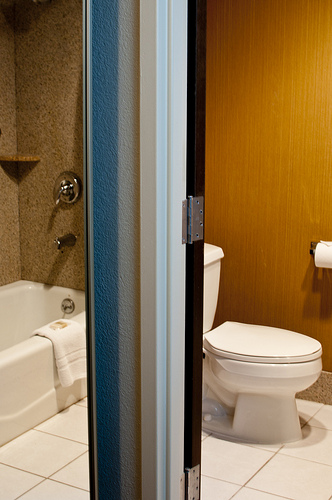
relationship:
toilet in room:
[206, 247, 327, 446] [200, 5, 331, 497]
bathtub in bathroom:
[0, 277, 87, 449] [3, 3, 90, 484]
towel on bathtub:
[34, 317, 85, 407] [4, 277, 81, 442]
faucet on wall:
[53, 230, 76, 255] [15, 6, 85, 284]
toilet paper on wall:
[305, 233, 331, 283] [200, 5, 331, 497]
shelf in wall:
[0, 150, 40, 168] [4, 0, 81, 284]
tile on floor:
[2, 391, 331, 497] [2, 386, 331, 492]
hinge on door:
[183, 193, 207, 247] [182, 1, 209, 500]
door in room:
[182, 1, 209, 500] [200, 5, 331, 497]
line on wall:
[91, 6, 120, 496] [92, 0, 183, 499]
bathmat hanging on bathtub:
[35, 317, 86, 390] [4, 277, 81, 442]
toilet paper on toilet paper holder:
[305, 233, 331, 283] [305, 237, 331, 275]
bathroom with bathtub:
[3, 3, 90, 484] [0, 277, 87, 449]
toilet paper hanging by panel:
[305, 233, 331, 283] [202, 0, 329, 372]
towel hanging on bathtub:
[34, 317, 85, 407] [4, 277, 81, 442]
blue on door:
[91, 1, 118, 498] [87, 0, 170, 500]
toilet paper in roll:
[305, 233, 331, 283] [308, 241, 331, 281]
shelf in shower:
[0, 150, 40, 168] [4, 0, 81, 284]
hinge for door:
[183, 193, 207, 247] [182, 1, 209, 500]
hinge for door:
[183, 464, 200, 497] [182, 1, 209, 500]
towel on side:
[34, 317, 85, 407] [1, 332, 89, 438]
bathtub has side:
[0, 277, 87, 449] [1, 332, 89, 438]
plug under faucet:
[60, 297, 72, 315] [53, 230, 76, 255]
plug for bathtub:
[60, 297, 72, 315] [0, 277, 87, 449]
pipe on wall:
[54, 232, 77, 253] [15, 6, 85, 284]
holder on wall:
[307, 240, 331, 276] [199, 1, 328, 408]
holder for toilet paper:
[307, 240, 331, 276] [305, 233, 331, 283]